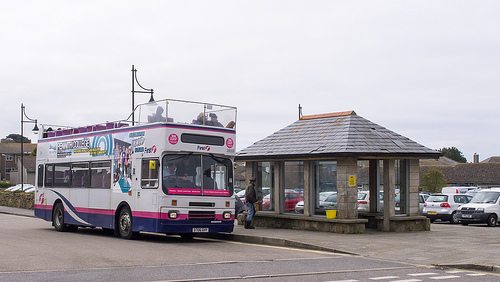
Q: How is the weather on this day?
A: It is overcast.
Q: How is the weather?
A: It is overcast.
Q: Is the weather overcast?
A: Yes, it is overcast.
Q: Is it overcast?
A: Yes, it is overcast.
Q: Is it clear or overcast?
A: It is overcast.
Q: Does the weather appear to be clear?
A: No, it is overcast.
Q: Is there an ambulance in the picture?
A: No, there are no ambulances.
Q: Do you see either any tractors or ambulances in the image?
A: No, there are no ambulances or tractors.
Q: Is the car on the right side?
A: Yes, the car is on the right of the image.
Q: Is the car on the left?
A: No, the car is on the right of the image.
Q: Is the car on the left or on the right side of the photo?
A: The car is on the right of the image.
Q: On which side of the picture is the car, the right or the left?
A: The car is on the right of the image.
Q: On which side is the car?
A: The car is on the right of the image.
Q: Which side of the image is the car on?
A: The car is on the right of the image.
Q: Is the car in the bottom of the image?
A: Yes, the car is in the bottom of the image.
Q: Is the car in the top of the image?
A: No, the car is in the bottom of the image.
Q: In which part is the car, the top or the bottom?
A: The car is in the bottom of the image.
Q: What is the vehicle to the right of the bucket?
A: The vehicle is a car.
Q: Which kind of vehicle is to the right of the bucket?
A: The vehicle is a car.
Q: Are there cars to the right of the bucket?
A: Yes, there is a car to the right of the bucket.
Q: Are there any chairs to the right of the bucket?
A: No, there is a car to the right of the bucket.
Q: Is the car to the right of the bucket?
A: Yes, the car is to the right of the bucket.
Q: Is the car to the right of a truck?
A: No, the car is to the right of the bucket.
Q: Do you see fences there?
A: No, there are no fences.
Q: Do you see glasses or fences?
A: No, there are no fences or glasses.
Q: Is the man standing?
A: Yes, the man is standing.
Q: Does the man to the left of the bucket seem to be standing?
A: Yes, the man is standing.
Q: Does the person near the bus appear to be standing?
A: Yes, the man is standing.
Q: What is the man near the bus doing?
A: The man is standing.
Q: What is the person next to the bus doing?
A: The man is standing.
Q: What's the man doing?
A: The man is standing.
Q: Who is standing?
A: The man is standing.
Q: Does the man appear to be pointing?
A: No, the man is standing.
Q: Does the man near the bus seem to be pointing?
A: No, the man is standing.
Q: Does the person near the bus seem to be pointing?
A: No, the man is standing.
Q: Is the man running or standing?
A: The man is standing.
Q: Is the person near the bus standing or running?
A: The man is standing.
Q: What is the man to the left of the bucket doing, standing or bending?
A: The man is standing.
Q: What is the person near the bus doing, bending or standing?
A: The man is standing.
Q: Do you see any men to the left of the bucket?
A: Yes, there is a man to the left of the bucket.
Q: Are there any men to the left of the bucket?
A: Yes, there is a man to the left of the bucket.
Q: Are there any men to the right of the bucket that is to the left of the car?
A: No, the man is to the left of the bucket.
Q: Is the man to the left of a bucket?
A: Yes, the man is to the left of a bucket.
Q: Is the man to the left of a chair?
A: No, the man is to the left of a bucket.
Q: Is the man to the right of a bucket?
A: No, the man is to the left of a bucket.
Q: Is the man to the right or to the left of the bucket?
A: The man is to the left of the bucket.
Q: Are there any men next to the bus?
A: Yes, there is a man next to the bus.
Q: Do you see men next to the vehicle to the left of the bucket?
A: Yes, there is a man next to the bus.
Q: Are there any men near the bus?
A: Yes, there is a man near the bus.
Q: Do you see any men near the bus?
A: Yes, there is a man near the bus.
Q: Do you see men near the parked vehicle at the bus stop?
A: Yes, there is a man near the bus.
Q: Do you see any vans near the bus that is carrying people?
A: No, there is a man near the bus.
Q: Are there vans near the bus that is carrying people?
A: No, there is a man near the bus.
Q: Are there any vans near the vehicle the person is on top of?
A: No, there is a man near the bus.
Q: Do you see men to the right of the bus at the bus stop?
A: Yes, there is a man to the right of the bus.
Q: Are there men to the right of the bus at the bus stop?
A: Yes, there is a man to the right of the bus.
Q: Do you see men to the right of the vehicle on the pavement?
A: Yes, there is a man to the right of the bus.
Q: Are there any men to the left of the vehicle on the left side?
A: No, the man is to the right of the bus.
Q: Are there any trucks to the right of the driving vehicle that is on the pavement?
A: No, there is a man to the right of the bus.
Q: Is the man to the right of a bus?
A: Yes, the man is to the right of a bus.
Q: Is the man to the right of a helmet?
A: No, the man is to the right of a bus.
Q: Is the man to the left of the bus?
A: No, the man is to the right of the bus.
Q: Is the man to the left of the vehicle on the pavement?
A: No, the man is to the right of the bus.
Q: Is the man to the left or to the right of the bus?
A: The man is to the right of the bus.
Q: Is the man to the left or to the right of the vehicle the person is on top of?
A: The man is to the right of the bus.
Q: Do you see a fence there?
A: No, there are no fences.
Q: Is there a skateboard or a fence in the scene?
A: No, there are no fences or skateboards.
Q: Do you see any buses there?
A: Yes, there is a bus.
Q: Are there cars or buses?
A: Yes, there is a bus.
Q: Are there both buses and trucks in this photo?
A: No, there is a bus but no trucks.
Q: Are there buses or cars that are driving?
A: Yes, the bus is driving.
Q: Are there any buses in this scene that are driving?
A: Yes, there is a bus that is driving.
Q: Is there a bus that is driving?
A: Yes, there is a bus that is driving.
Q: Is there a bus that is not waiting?
A: Yes, there is a bus that is driving.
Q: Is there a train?
A: No, there are no trains.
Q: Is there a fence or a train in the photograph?
A: No, there are no trains or fences.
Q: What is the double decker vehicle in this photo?
A: The vehicle is a bus.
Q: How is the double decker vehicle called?
A: The vehicle is a bus.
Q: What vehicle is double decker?
A: The vehicle is a bus.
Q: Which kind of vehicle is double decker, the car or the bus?
A: The bus is double decker.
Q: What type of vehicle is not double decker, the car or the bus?
A: The car is not double decker.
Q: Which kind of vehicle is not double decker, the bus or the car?
A: The car is not double decker.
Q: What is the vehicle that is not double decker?
A: The vehicle is a car.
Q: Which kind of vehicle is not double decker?
A: The vehicle is a car.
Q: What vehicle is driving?
A: The vehicle is a bus.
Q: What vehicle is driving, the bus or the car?
A: The bus is driving.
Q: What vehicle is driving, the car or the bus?
A: The bus is driving.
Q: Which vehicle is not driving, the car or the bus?
A: The car is not driving.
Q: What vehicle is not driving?
A: The vehicle is a car.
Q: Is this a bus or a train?
A: This is a bus.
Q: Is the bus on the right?
A: No, the bus is on the left of the image.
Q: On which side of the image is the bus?
A: The bus is on the left of the image.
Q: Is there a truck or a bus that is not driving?
A: No, there is a bus but it is driving.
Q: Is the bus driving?
A: Yes, the bus is driving.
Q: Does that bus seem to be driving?
A: Yes, the bus is driving.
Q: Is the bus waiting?
A: No, the bus is driving.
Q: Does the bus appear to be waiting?
A: No, the bus is driving.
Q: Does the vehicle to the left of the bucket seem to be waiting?
A: No, the bus is driving.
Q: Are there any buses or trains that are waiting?
A: No, there is a bus but it is driving.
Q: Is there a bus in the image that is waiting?
A: No, there is a bus but it is driving.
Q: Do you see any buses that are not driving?
A: No, there is a bus but it is driving.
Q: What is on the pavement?
A: The bus is on the pavement.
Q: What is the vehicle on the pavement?
A: The vehicle is a bus.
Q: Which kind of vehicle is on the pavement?
A: The vehicle is a bus.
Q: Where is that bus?
A: The bus is on the pavement.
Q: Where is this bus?
A: The bus is at the bus stop.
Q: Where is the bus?
A: The bus is at the bus stop.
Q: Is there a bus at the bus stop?
A: Yes, there is a bus at the bus stop.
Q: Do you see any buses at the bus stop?
A: Yes, there is a bus at the bus stop.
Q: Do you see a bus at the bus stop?
A: Yes, there is a bus at the bus stop.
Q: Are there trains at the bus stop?
A: No, there is a bus at the bus stop.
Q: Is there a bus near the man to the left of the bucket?
A: Yes, there is a bus near the man.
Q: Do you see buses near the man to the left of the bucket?
A: Yes, there is a bus near the man.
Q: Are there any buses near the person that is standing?
A: Yes, there is a bus near the man.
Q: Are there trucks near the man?
A: No, there is a bus near the man.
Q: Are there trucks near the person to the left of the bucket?
A: No, there is a bus near the man.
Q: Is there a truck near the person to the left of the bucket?
A: No, there is a bus near the man.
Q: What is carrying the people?
A: The bus is carrying the people.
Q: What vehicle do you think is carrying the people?
A: The vehicle is a bus.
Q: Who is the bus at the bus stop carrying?
A: The bus is carrying people.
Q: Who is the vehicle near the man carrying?
A: The bus is carrying people.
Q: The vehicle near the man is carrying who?
A: The bus is carrying people.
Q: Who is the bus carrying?
A: The bus is carrying people.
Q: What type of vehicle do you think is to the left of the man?
A: The vehicle is a bus.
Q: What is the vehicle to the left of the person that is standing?
A: The vehicle is a bus.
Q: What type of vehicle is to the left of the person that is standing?
A: The vehicle is a bus.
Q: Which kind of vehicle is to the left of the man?
A: The vehicle is a bus.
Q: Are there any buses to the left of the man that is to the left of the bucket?
A: Yes, there is a bus to the left of the man.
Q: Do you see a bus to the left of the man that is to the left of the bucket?
A: Yes, there is a bus to the left of the man.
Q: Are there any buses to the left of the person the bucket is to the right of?
A: Yes, there is a bus to the left of the man.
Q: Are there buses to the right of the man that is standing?
A: No, the bus is to the left of the man.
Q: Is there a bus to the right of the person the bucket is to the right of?
A: No, the bus is to the left of the man.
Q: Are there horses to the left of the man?
A: No, there is a bus to the left of the man.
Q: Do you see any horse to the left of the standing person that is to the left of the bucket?
A: No, there is a bus to the left of the man.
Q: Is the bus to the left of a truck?
A: No, the bus is to the left of the man.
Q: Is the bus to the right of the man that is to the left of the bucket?
A: No, the bus is to the left of the man.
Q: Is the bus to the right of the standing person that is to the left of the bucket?
A: No, the bus is to the left of the man.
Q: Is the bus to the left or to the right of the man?
A: The bus is to the left of the man.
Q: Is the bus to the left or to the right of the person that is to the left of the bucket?
A: The bus is to the left of the man.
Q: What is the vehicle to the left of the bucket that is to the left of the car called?
A: The vehicle is a bus.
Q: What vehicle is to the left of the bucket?
A: The vehicle is a bus.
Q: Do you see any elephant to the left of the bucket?
A: No, there is a bus to the left of the bucket.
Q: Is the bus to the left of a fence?
A: No, the bus is to the left of a bucket.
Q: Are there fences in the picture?
A: No, there are no fences.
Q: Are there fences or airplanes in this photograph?
A: No, there are no fences or airplanes.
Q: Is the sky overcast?
A: Yes, the sky is overcast.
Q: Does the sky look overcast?
A: Yes, the sky is overcast.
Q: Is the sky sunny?
A: No, the sky is overcast.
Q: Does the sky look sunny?
A: No, the sky is overcast.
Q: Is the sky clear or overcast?
A: The sky is overcast.